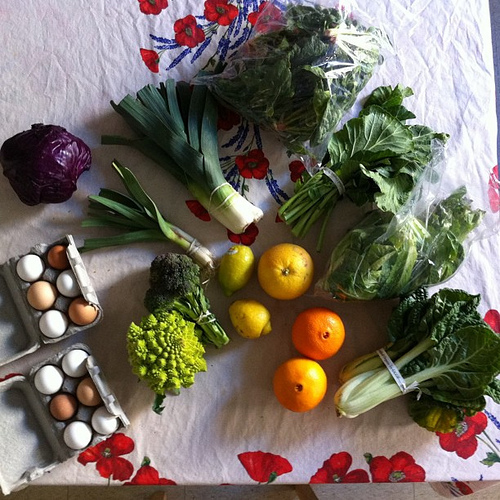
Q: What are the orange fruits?
A: Oranges.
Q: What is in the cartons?
A: Eggs.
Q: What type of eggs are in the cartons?
A: White and brown.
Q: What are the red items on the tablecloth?
A: Flowers.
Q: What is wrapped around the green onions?
A: Rubber band.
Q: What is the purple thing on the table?
A: Cabbage.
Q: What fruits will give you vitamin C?
A: Lemons and Oranges.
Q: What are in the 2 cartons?
A: Eggs.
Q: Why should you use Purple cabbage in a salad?
A: It adds color and excitement.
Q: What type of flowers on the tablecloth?
A: Red Poppies.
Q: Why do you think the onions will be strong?
A: They are large.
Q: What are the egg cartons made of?
A: Cardboard.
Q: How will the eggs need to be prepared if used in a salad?
A: Boiled.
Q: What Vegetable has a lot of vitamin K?
A: Broccoli.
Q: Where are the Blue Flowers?
A: Next to the Red Peonies on Tablecloth.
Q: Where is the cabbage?
A: On the table.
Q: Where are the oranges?
A: On the table.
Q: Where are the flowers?
A: On the table cloth.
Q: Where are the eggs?
A: In the cartons.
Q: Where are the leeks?
A: On the table.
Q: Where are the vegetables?
A: On the table.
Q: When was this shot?
A: Daytime.